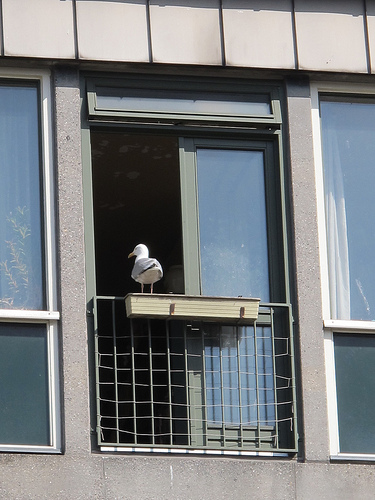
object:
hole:
[187, 355, 203, 371]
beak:
[128, 243, 164, 293]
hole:
[221, 357, 239, 372]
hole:
[135, 370, 150, 385]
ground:
[323, 118, 331, 140]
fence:
[88, 294, 299, 457]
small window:
[88, 76, 283, 124]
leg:
[141, 283, 144, 293]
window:
[0, 67, 62, 451]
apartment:
[0, 0, 375, 500]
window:
[80, 74, 303, 462]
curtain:
[317, 94, 351, 320]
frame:
[0, 66, 63, 453]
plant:
[0, 204, 46, 311]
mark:
[0, 461, 173, 499]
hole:
[98, 337, 114, 355]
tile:
[0, 0, 375, 77]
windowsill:
[88, 443, 299, 463]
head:
[128, 244, 149, 259]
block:
[125, 291, 261, 324]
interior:
[89, 125, 190, 448]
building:
[0, 0, 375, 500]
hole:
[99, 400, 116, 418]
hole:
[117, 403, 134, 417]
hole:
[169, 354, 186, 371]